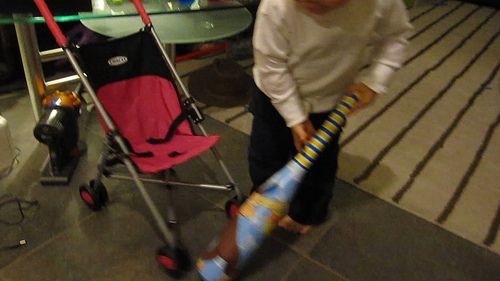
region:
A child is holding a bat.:
[187, 0, 409, 275]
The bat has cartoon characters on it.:
[195, 86, 385, 271]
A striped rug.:
[390, 40, 495, 250]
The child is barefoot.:
[215, 167, 357, 239]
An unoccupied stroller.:
[45, 0, 265, 270]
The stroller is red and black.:
[55, 0, 250, 262]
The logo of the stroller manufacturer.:
[101, 46, 131, 71]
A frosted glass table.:
[60, 2, 250, 49]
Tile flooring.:
[0, 147, 445, 268]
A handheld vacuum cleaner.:
[25, 78, 95, 184]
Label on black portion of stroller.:
[93, 56, 145, 68]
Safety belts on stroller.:
[122, 106, 195, 161]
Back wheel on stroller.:
[80, 176, 111, 217]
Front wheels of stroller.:
[155, 196, 245, 278]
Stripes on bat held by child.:
[293, 83, 354, 169]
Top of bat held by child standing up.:
[202, 158, 283, 280]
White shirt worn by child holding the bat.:
[263, 16, 387, 78]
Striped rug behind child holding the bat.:
[348, 4, 495, 178]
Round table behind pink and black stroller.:
[86, 1, 256, 35]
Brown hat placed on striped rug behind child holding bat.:
[179, 56, 261, 118]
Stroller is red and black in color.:
[80, 43, 207, 190]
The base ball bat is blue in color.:
[238, 124, 339, 245]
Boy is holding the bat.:
[250, 12, 374, 189]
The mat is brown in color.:
[407, 78, 492, 190]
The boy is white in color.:
[267, 21, 359, 77]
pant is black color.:
[261, 111, 290, 152]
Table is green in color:
[168, 11, 231, 44]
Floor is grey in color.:
[329, 220, 426, 270]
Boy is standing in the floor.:
[248, 98, 353, 270]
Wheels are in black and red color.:
[71, 180, 116, 211]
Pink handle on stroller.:
[36, 1, 70, 49]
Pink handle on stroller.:
[131, 0, 156, 27]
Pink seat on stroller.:
[96, 70, 220, 175]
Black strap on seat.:
[146, 110, 193, 146]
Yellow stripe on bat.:
[291, 152, 313, 168]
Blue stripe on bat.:
[302, 140, 319, 152]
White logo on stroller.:
[101, 51, 133, 68]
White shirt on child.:
[252, 1, 420, 128]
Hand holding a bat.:
[284, 116, 317, 151]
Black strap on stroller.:
[116, 132, 156, 161]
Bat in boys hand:
[160, 67, 368, 278]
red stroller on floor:
[55, 0, 235, 276]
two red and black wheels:
[66, 157, 128, 234]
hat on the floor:
[185, 42, 256, 118]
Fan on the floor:
[27, 86, 88, 215]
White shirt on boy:
[242, 1, 419, 149]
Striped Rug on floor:
[413, 18, 495, 250]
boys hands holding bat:
[288, 77, 414, 169]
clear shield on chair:
[75, 0, 257, 46]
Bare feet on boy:
[277, 205, 355, 255]